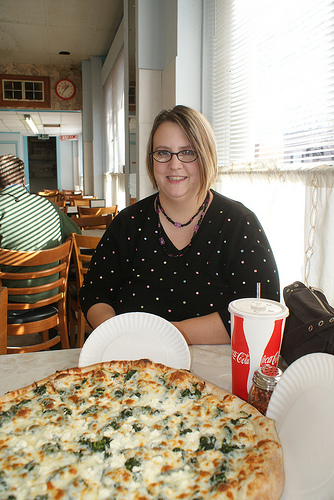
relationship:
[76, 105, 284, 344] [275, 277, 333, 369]
woman has a purse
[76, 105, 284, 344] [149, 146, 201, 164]
woman has glasses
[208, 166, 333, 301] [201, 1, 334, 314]
curtain over window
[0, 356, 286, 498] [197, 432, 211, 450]
pizza has olives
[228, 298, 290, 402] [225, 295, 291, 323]
cup has a lid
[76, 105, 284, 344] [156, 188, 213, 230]
woman has necklace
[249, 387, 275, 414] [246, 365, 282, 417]
red pepper in jar